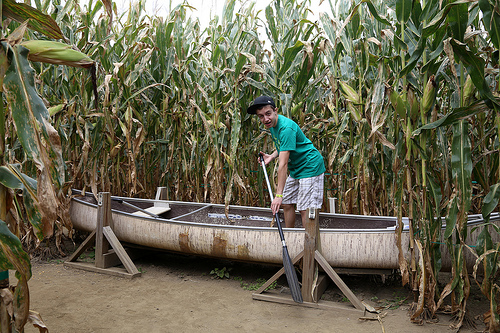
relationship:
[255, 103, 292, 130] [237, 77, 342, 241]
face on person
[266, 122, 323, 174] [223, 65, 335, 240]
shirt on man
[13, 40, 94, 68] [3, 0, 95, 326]
corn on corn stalk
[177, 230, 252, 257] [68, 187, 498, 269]
stains on side of boat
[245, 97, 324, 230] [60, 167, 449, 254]
boy in canoe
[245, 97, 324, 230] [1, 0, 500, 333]
boy in corn field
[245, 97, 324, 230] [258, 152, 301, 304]
boy holding an oar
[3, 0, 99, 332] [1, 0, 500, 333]
corn stalk in corn field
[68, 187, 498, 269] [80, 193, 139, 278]
boat in stands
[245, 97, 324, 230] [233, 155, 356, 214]
boy in shorts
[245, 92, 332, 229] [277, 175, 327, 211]
boy with shorts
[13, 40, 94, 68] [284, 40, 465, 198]
corn in field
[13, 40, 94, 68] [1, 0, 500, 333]
corn in corn field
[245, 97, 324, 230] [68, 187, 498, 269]
boy in a boat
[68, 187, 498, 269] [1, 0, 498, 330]
boat in a corn field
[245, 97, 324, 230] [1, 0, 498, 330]
boy in a corn field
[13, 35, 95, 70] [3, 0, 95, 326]
corn on corn stalk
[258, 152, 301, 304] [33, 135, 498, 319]
oar to oar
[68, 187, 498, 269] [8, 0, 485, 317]
boat in field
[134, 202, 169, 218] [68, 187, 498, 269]
bench in boat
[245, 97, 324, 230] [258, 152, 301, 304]
boy holding oar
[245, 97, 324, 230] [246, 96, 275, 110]
boy wearing cap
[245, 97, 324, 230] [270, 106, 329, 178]
boy wearing shirt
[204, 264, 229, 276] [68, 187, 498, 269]
green plant under boat